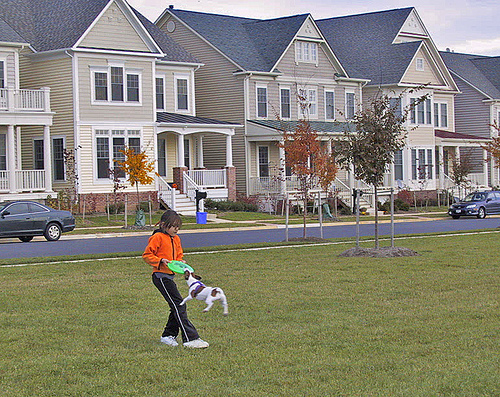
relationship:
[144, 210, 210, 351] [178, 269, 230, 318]
girl playing frisbee with dog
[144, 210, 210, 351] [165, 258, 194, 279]
girl holding frisbee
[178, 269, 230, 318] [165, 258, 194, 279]
dog biting on frisbee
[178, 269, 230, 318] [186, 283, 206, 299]
dog has patch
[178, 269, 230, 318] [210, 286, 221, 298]
dog has patch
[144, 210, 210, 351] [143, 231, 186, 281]
girl has jacket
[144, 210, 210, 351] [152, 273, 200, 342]
girl has pants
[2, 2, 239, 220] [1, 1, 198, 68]
house has roof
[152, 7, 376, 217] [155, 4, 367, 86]
house has roof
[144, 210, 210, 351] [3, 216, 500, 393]
girl in park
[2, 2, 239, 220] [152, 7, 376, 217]
house next to house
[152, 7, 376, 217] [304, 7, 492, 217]
house next to house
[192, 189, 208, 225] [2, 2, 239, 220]
mailbox in front of house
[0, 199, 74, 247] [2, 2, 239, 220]
car parked near house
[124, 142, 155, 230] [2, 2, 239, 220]
tree in front of house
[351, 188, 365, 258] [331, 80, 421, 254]
support pole next to tree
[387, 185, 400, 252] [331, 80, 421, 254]
support pole next to tree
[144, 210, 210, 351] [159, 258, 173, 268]
girl has hand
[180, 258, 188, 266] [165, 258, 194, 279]
hand holding frisbee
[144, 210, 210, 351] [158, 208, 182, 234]
girl has hair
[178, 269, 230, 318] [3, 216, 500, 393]
dog up above park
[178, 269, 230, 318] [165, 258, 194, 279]
dog holding frisbee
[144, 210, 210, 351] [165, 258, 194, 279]
girl playing with frisbee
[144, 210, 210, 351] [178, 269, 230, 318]
girl playing with dog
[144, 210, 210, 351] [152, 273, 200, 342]
girl wearing pants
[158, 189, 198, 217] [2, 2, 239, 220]
steps on house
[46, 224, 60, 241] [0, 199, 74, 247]
rear tire on parked car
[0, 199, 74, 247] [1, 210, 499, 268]
car beside road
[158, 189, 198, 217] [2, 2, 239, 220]
steps in front of house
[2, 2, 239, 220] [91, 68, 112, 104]
house has window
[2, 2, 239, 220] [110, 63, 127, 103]
house has window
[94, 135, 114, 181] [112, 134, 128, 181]
window next to window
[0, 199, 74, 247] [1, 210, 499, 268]
car parked beside road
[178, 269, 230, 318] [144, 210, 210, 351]
dog playing with girl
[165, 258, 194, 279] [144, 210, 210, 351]
frisbee next to girl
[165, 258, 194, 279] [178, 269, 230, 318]
frisbee next to dog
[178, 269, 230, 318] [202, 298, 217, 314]
dog has left hind leg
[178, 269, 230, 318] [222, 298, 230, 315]
dog has right hind leg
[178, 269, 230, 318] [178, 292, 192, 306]
dog has left front leg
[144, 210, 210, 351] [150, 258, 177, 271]
girl has lower torso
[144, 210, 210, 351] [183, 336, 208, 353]
girl has right foot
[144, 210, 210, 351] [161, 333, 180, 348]
girl has left foot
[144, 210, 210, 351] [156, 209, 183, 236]
girl has head